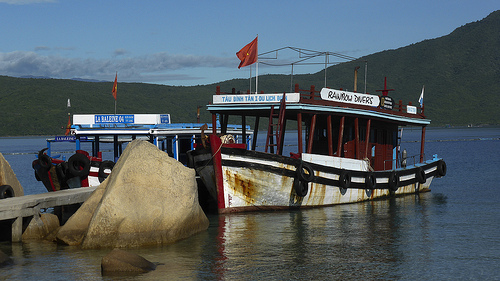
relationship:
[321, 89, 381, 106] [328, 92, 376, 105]
words say rainbow divers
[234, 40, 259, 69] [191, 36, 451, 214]
flag on top of boat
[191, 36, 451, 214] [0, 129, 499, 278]
boat inside water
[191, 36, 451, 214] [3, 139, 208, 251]
boat beside docks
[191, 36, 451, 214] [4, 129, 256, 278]
boat by shore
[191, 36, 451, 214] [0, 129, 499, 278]
boat on top of water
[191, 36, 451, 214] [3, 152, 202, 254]
boat sitting at docks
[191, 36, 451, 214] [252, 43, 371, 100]
boat covered with gazebo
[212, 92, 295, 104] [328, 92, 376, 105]
sign says rainbow divers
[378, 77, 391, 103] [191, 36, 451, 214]
ladder on top of boat